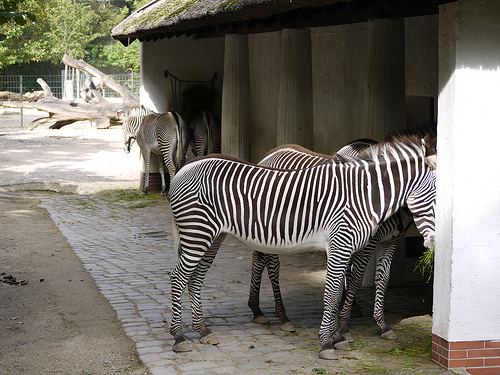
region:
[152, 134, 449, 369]
a zebra standing near another zebra.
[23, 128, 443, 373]
a paved sidewalk.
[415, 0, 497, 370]
a white cement pillar.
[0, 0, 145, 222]
A zoo with lots of trees.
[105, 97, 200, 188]
A zebra near a sidewalk.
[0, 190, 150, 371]
a small paved road.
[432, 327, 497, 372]
the bottom of a pillar.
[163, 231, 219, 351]
a hind right zebra leg.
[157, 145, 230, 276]
the rear end of a zebra.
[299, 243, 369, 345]
the right leg of a zebra.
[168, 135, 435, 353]
three standing zebras in a row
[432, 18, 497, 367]
wall with brick base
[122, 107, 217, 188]
backs of two zebra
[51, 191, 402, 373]
cobblestones on ground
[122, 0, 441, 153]
three columns under roof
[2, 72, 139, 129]
pole on wire fence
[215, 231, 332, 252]
white belly of zebra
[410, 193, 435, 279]
grass in zebra mouth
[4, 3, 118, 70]
green leaves on trees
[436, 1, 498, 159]
shadow on wall edge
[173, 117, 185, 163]
Tail of striped zebra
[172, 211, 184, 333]
Part of striped zebra leg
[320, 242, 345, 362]
Leg of striped zebra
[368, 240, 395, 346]
Leg of striped zebra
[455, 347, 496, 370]
Part of brick foundation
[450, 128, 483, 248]
Part of brick wall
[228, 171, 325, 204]
Back of striped zebra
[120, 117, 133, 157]
Head of striped zebra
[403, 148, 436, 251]
Part pf striped zebra head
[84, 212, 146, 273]
Paving blocks for zebra area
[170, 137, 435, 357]
zebra eating food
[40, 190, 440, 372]
cobbled walkway for zebras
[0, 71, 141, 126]
green fence in background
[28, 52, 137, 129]
large dead drift wood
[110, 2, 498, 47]
dirty roof above zebras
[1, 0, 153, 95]
green trees off in distance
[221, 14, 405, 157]
three colums holding up roof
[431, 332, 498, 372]
red brick foundation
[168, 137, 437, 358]
three zebras eating side by side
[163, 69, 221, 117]
holds hay for zebras to eat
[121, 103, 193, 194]
The zebra is looking away from the viewer.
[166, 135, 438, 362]
The zebra has black stripes.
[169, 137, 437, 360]
The zebra's head is partially hidden by a wall.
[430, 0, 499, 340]
The wall is white.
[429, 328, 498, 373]
The bottom of the wall is red brick.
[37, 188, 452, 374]
The ground is made of gray stones.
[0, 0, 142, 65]
The tree leaves are green.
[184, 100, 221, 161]
The zebra is hidden by shadow.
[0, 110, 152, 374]
The ground is not paved.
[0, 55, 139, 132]
Tree trunks lie on the ground.